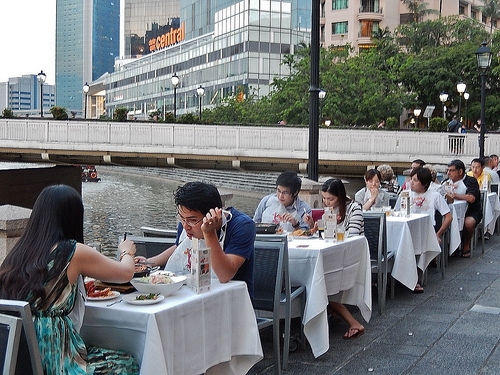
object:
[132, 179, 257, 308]
man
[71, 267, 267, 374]
table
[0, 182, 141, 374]
woman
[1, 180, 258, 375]
man and woman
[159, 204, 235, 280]
napkin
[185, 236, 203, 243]
chin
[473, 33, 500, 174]
light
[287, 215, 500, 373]
sidewalk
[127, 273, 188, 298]
bowl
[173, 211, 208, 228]
glasses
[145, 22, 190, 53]
sign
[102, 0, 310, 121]
building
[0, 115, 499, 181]
bridge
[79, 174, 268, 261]
water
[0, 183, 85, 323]
hair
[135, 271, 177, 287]
rice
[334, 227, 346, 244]
mug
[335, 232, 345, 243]
beer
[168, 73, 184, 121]
lights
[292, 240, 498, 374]
street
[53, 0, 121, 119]
buildings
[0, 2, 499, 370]
city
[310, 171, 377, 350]
woman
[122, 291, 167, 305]
bowl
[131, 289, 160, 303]
salad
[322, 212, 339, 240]
menu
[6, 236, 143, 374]
dress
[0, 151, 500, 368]
outdoors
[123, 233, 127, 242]
chop sticks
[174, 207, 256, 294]
blue shirt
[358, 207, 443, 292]
tables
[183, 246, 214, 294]
menu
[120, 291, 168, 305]
dishes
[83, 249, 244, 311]
dinner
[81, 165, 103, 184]
boat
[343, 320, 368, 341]
foot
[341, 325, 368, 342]
sandal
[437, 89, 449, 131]
lights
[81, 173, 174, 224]
quakes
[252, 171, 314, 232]
man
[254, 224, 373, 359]
table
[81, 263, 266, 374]
tablecloths